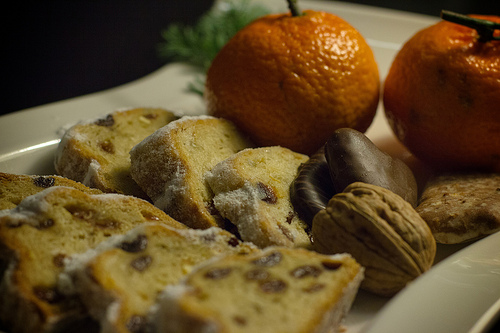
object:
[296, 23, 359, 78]
light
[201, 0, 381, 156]
orange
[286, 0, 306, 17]
stem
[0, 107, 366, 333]
bread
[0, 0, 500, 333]
food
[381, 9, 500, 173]
orange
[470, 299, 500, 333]
edge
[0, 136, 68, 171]
light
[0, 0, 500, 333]
plate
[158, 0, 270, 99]
leaves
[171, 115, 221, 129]
sugar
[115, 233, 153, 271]
spot